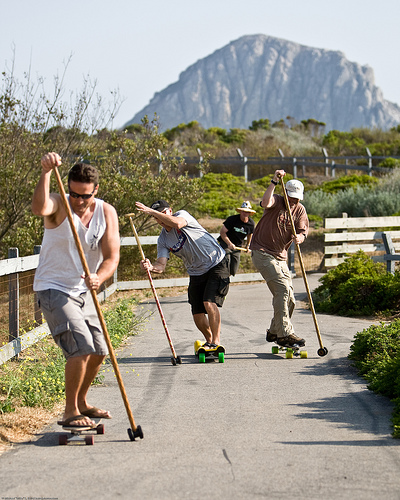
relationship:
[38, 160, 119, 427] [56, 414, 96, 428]
man wearing man's flipflops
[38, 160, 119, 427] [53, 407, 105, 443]
man on skateboard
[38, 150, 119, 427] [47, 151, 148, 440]
man holding pole with wheels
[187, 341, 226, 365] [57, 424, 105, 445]
skateboard with colorful wheels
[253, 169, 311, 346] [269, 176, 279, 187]
man wearing black watch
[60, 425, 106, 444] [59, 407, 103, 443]
red wheels on skateboard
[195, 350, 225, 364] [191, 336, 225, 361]
wheels are green on skateboard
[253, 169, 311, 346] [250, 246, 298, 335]
man wearing tan pants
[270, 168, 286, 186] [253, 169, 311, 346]
hand of man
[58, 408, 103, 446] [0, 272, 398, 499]
skateboard on paved path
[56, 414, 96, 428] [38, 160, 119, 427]
man's flipflops worn by man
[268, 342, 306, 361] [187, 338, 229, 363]
bright green wheels on skateboard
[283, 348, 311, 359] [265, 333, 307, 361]
wheels are yellow on skateboard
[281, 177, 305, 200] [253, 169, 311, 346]
hat on man